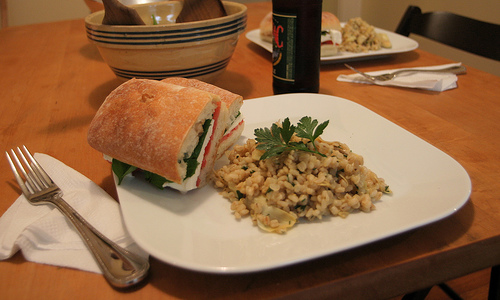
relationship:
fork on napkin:
[3, 141, 151, 291] [12, 213, 64, 248]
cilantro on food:
[254, 115, 330, 163] [85, 71, 393, 233]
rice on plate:
[207, 119, 391, 234] [142, 100, 490, 251]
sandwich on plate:
[87, 75, 245, 193] [110, 90, 475, 281]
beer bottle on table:
[271, 0, 324, 95] [0, 19, 499, 297]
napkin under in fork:
[2, 150, 149, 277] [3, 141, 151, 291]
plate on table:
[241, 9, 418, 66] [0, 19, 499, 297]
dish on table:
[109, 93, 471, 275] [0, 19, 499, 297]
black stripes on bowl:
[110, 55, 232, 80] [84, 0, 246, 85]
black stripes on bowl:
[86, 14, 246, 45] [84, 0, 246, 85]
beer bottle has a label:
[271, 0, 324, 95] [265, 10, 299, 87]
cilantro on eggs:
[253, 115, 330, 161] [211, 121, 393, 230]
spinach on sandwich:
[105, 165, 185, 188] [79, 77, 242, 208]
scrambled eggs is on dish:
[207, 115, 392, 232] [109, 93, 471, 275]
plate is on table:
[244, 21, 419, 61] [0, 19, 499, 297]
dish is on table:
[109, 93, 471, 275] [0, 19, 499, 297]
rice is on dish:
[224, 118, 389, 232] [109, 93, 471, 275]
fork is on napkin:
[3, 141, 151, 291] [2, 150, 149, 277]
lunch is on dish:
[99, 74, 384, 221] [109, 93, 471, 275]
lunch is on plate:
[85, 75, 392, 235] [110, 90, 475, 281]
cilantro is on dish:
[253, 115, 330, 161] [109, 93, 471, 275]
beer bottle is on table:
[271, 0, 320, 95] [0, 19, 499, 297]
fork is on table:
[4, 144, 151, 290] [0, 19, 499, 297]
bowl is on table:
[84, 24, 262, 96] [0, 19, 499, 297]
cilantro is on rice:
[253, 115, 330, 161] [207, 118, 390, 234]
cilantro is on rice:
[253, 115, 330, 161] [339, 15, 392, 53]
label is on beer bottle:
[268, 8, 298, 81] [271, 0, 324, 95]